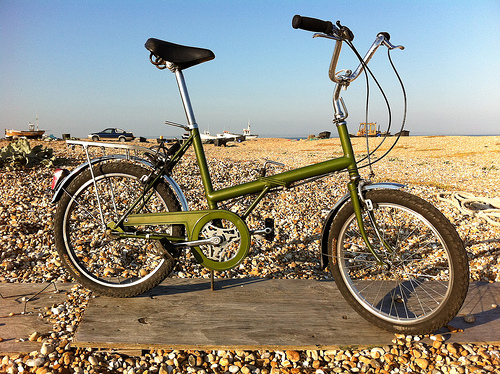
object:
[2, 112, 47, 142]
sailboat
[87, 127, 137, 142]
car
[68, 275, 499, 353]
wood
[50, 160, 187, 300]
wheel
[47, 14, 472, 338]
bike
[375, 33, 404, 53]
brake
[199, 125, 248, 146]
sailboat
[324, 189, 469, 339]
wheel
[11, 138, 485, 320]
rock